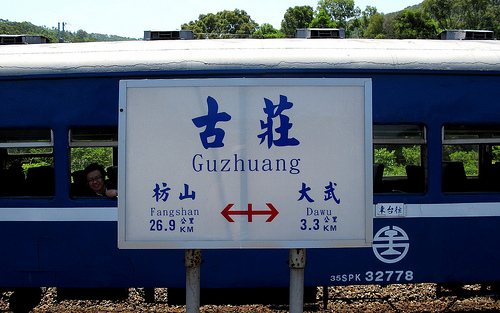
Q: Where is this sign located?
A: China.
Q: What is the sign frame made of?
A: Metal.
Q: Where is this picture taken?
A: Train station.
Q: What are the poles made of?
A: Metal.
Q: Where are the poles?
A: Under the sign.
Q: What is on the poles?
A: A sign.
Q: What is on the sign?
A: Writing and arrows.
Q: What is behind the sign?
A: The train.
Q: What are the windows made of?
A: Glass.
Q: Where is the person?
A: In the train.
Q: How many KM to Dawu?
A: 3.3.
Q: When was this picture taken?
A: Daytime.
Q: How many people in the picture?
A: 1.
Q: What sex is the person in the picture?
A: Male.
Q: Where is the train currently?
A: Guzhuang.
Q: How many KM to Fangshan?
A: 26.9.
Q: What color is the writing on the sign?
A: Blue.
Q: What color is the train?
A: Blue.